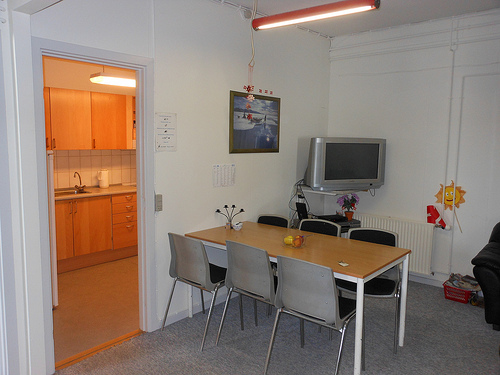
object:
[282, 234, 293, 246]
produce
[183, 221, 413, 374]
table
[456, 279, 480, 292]
objects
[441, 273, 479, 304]
baskets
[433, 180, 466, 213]
sun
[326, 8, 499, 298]
wall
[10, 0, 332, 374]
wall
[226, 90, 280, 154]
painting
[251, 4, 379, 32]
light fixture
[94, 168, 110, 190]
pitcher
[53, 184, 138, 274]
counter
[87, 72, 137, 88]
light fixture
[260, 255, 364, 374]
chairs